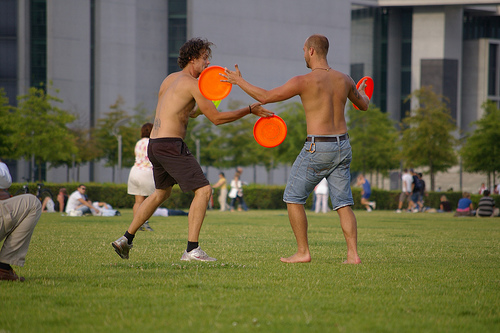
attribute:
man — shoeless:
[222, 28, 382, 268]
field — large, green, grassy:
[1, 206, 498, 328]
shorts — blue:
[283, 131, 355, 210]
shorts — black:
[146, 137, 208, 194]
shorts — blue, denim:
[277, 137, 357, 217]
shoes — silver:
[182, 235, 215, 263]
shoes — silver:
[113, 230, 133, 258]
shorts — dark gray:
[144, 135, 214, 195]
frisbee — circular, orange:
[252, 112, 288, 147]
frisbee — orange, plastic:
[194, 63, 233, 103]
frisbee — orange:
[196, 65, 230, 100]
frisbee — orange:
[346, 75, 376, 107]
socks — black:
[122, 229, 197, 251]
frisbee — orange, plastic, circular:
[249, 111, 291, 151]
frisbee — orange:
[198, 66, 234, 98]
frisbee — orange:
[351, 74, 373, 108]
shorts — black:
[143, 130, 210, 199]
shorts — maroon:
[140, 132, 217, 195]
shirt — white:
[64, 190, 86, 209]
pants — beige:
[2, 185, 50, 288]